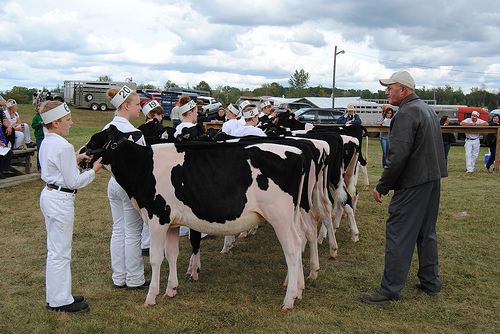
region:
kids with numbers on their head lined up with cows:
[29, 77, 371, 317]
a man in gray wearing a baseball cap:
[361, 75, 459, 303]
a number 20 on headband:
[106, 85, 131, 111]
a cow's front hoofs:
[136, 284, 183, 309]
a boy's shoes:
[50, 292, 90, 317]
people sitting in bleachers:
[0, 95, 40, 180]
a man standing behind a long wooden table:
[459, 110, 486, 178]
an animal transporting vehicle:
[61, 80, 139, 109]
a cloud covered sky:
[6, 2, 498, 100]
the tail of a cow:
[318, 151, 334, 218]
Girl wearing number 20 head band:
[96, 83, 154, 292]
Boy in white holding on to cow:
[32, 95, 310, 315]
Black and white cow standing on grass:
[73, 121, 315, 308]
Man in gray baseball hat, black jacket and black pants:
[358, 67, 454, 304]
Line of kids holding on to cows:
[29, 88, 369, 313]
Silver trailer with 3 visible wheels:
[60, 75, 142, 112]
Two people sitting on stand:
[1, 90, 36, 190]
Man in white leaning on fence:
[456, 105, 490, 177]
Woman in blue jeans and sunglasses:
[371, 104, 405, 169]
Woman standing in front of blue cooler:
[480, 110, 497, 170]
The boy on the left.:
[30, 96, 103, 322]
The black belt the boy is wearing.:
[48, 181, 78, 194]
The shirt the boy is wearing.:
[43, 129, 92, 191]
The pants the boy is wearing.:
[43, 187, 76, 304]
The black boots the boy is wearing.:
[50, 295, 87, 314]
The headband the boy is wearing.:
[39, 105, 72, 123]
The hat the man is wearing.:
[380, 65, 414, 90]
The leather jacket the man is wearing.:
[382, 96, 444, 187]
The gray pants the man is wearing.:
[391, 187, 437, 292]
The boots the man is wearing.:
[361, 277, 439, 301]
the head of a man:
[378, 45, 423, 114]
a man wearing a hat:
[369, 37, 456, 109]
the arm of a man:
[356, 100, 443, 202]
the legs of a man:
[351, 157, 461, 308]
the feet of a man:
[360, 246, 450, 307]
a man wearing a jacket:
[356, 95, 458, 208]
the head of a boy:
[26, 80, 123, 147]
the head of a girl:
[108, 51, 191, 128]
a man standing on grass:
[328, 60, 471, 317]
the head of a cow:
[67, 103, 150, 201]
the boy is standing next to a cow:
[31, 95, 106, 315]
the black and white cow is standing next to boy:
[76, 122, 326, 313]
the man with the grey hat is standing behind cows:
[362, 64, 451, 311]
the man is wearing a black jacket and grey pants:
[355, 65, 463, 307]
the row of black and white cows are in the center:
[65, 108, 370, 311]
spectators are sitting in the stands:
[1, 86, 34, 178]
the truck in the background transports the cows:
[59, 74, 145, 115]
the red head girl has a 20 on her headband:
[98, 78, 158, 299]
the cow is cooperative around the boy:
[70, 120, 325, 315]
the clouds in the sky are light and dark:
[0, 0, 499, 96]